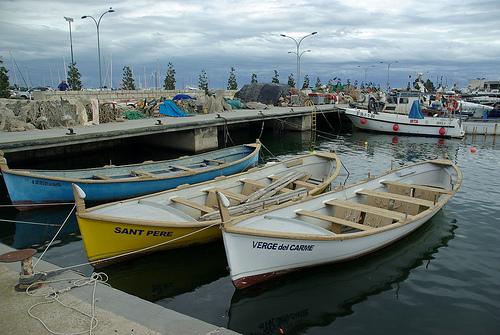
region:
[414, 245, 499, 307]
ripples in the water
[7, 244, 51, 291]
posts boats are tied to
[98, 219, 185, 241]
name on a boat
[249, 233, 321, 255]
name on a boat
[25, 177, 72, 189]
name on a boat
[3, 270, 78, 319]
concrete where boats are tied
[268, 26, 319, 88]
poles with lights on them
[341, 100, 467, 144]
boat behind other boats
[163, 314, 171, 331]
edge of a dork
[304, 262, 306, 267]
part of a boat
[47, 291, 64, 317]
part of a rope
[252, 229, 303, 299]
part of a kline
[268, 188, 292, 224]
pat of a boar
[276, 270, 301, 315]
part of a water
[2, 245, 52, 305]
A steel holding the ties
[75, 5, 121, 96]
A tall lamp post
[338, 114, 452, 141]
Red balloons beside the boat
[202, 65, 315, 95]
There are green trees along the road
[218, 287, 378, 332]
Reflection of the boat on the black water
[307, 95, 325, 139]
A yellow small stairs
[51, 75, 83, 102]
A man with blue shirt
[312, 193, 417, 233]
A wooden bench at the center of the boat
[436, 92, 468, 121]
An orange life saver hanging up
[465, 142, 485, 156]
An orange buoy is floating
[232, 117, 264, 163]
boat in the water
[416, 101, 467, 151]
boat in the water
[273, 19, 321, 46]
lights on the pole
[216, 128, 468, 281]
white boat with wooden seats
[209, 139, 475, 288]
white boat with wooden seats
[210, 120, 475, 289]
white boat with wooden seats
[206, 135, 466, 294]
white boat with wooden seats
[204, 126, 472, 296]
white boat with wooden seats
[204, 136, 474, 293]
white boat with wooden seats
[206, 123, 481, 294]
white boat with wooden seats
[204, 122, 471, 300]
white boat with wooden seats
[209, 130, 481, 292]
white boat with wooden seats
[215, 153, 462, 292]
the boat is white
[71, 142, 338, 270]
the boat is yellow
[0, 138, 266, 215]
the boat is blue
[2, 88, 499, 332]
the boats on the water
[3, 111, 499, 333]
the water is dark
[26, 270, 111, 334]
the rope is white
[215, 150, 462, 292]
the seats on the boat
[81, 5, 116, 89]
the double street light is tall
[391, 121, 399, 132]
the buoy is red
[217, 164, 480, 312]
A white boat is in the water.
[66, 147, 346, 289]
A yellow boat is in the water.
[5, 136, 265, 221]
A blue boat is in the water.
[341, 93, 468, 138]
A small white boat is in the water.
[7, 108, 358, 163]
A long dock is next to the boats.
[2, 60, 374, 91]
A line of green trees can be seen near the dock.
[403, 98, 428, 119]
A blue tarp is on the white boat.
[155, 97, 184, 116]
A blue tarp is on the dock.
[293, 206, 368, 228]
The white boat has wooden seats.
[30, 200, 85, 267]
The yellow boat is ankered to the dock by rope.